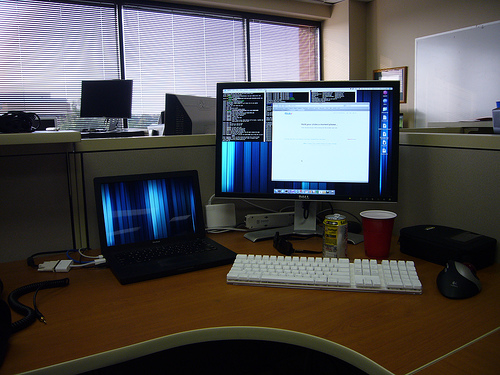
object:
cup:
[359, 208, 398, 259]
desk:
[2, 216, 500, 370]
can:
[324, 212, 348, 258]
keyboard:
[227, 254, 423, 296]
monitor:
[213, 78, 404, 202]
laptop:
[92, 168, 235, 286]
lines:
[120, 182, 131, 243]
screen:
[96, 174, 201, 246]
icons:
[383, 90, 388, 97]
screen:
[223, 83, 393, 194]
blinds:
[1, 0, 121, 129]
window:
[114, 0, 246, 124]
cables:
[55, 258, 105, 272]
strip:
[245, 212, 294, 228]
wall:
[7, 138, 500, 252]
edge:
[28, 324, 393, 374]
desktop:
[212, 78, 405, 240]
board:
[412, 20, 500, 126]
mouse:
[437, 262, 482, 301]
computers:
[215, 79, 422, 296]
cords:
[10, 275, 73, 336]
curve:
[26, 323, 397, 373]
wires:
[27, 247, 85, 269]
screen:
[82, 81, 131, 118]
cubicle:
[1, 127, 499, 369]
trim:
[359, 209, 398, 219]